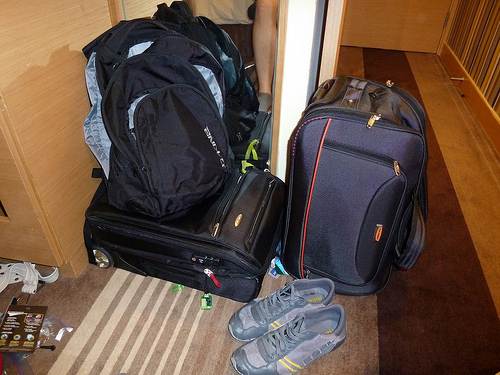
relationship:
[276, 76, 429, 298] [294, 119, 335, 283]
backpack with stripe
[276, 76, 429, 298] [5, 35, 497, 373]
backpack on floor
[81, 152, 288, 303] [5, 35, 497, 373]
bag on floor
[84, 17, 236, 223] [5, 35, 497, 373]
backpack on floor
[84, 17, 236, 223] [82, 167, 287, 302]
backpack on top of bag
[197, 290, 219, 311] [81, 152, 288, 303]
tag on a bag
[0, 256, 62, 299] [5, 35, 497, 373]
white belt on floor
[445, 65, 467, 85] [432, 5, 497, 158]
door stop attached to wall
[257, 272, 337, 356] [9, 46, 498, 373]
shoes on ground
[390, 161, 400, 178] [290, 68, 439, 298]
zipper on luggage